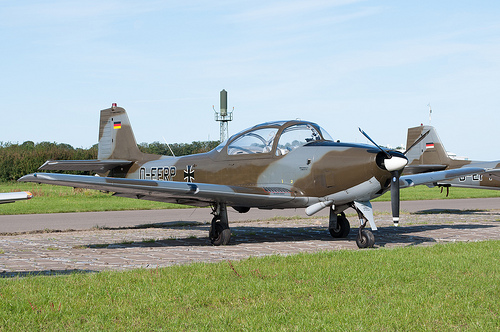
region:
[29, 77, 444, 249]
a small fighter jet on the runway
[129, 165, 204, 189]
black lettering on the jet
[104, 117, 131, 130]
a striped sticker on the plane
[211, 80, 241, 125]
a green tower behind the plane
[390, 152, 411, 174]
a white tip on the nose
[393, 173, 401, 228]
a black propeller blade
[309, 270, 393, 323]
green grass next to the runway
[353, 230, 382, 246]
small black wheels on the plane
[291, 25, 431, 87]
a bright blue sky overhead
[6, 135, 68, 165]
trees lined along the runway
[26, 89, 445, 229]
A vintage airplane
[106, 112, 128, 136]
The German flag on the tail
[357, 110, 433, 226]
Propeller on an airplane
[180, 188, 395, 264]
Wheels on an airplane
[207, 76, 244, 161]
A tower behind the plane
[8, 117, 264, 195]
Trees in the distance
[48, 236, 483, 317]
Grass in the foreground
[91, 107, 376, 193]
Camouflage paint on the plane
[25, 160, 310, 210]
The wing of an airplane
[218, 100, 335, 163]
Windows on an airplane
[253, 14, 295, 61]
part of a cloud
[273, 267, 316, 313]
part of a field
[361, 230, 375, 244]
part of a wheel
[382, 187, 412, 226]
part of a propellor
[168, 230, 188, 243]
part of a shade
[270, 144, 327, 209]
edge of a plane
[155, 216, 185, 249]
part of a shade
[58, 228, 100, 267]
part of a floor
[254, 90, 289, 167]
part of a cockpit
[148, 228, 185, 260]
part of a shade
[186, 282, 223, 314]
GRASS IS CUT VERY SHORT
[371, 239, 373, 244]
WHEEL IS BLACK ON THE PLANE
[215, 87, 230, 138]
TOWER ON THE OTHER SIDE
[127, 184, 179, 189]
WING IS ATTACHED TO THE SIDE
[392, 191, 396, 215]
THE PROPELLER IS ON THE FRONT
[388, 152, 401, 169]
THE SPINNER IS IN THE MIDDLE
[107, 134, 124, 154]
THE TAIL IS ON THE BACK OF THE PLANE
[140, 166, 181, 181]
WORDS ARE ON THE PLANE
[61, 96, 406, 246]
PLANE IS ON THE GROUND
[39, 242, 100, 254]
GROUND IS MADE OF GRAVITY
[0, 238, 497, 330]
a section of green grass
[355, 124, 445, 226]
an airplane propeller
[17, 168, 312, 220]
the wing of a plane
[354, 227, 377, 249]
the wheel of a plane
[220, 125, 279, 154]
part of a window of a plane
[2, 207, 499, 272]
part of a concrete area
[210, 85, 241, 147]
a large gray tower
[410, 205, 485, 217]
a black shadow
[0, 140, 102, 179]
a section of green trees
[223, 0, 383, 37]
part of a section of clouds